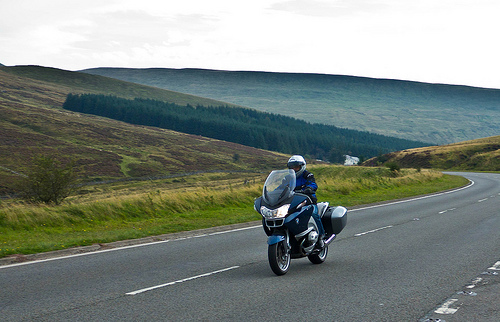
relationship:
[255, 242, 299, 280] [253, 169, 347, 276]
tire on bike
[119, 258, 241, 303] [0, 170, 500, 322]
line on road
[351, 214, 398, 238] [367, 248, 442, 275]
line on street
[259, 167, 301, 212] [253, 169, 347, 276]
windshield on bike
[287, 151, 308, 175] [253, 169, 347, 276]
helmet for bike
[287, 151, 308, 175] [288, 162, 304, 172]
helmet on head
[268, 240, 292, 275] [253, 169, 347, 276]
tire on bike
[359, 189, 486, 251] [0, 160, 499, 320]
stripe on highway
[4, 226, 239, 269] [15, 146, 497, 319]
edge of highway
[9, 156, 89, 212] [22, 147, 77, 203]
leaves of bush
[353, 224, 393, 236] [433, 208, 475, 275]
line on road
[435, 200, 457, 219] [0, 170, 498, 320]
line on road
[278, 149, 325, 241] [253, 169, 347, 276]
man riding bike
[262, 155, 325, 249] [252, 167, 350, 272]
man on bike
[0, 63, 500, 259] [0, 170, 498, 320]
grass by road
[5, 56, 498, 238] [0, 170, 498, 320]
grass by road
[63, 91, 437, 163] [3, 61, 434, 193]
trees on hill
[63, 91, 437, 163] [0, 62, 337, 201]
trees on hill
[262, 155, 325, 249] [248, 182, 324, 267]
man on motorcycle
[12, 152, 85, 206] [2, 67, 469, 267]
tree in field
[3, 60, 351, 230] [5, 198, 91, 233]
hill with grass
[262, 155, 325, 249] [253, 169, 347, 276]
man riding bike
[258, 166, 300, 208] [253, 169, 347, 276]
window on bike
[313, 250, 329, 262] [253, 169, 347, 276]
tire on bike